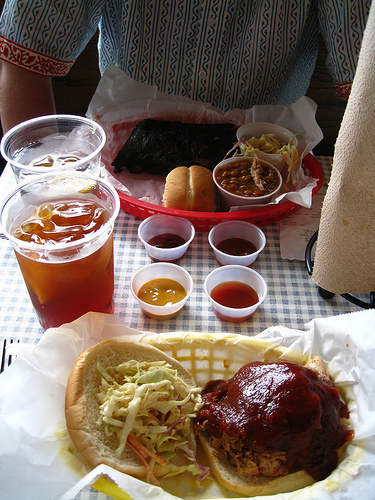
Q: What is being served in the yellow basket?
A: A burger.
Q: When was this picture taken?
A: During the day.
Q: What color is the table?
A: Blue and white.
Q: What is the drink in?
A: A cup.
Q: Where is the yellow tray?
A: On the table.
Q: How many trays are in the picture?
A: Two.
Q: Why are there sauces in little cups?
A: To be dipped in.